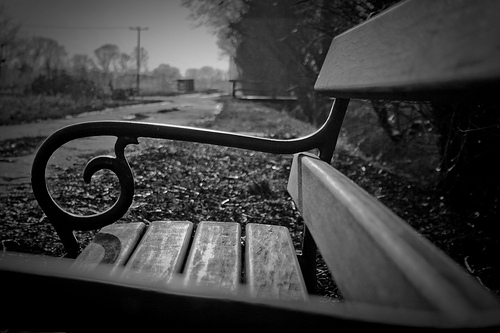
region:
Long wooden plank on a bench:
[305, 20, 468, 117]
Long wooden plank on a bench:
[271, 157, 428, 328]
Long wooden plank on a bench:
[240, 214, 307, 320]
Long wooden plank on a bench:
[189, 205, 240, 305]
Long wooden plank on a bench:
[140, 206, 185, 305]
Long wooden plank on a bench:
[67, 199, 133, 299]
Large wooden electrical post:
[124, 17, 159, 94]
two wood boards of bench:
[285, 0, 497, 307]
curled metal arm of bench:
[28, 99, 343, 232]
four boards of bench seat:
[70, 218, 304, 292]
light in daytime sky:
[3, 2, 234, 82]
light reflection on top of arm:
[58, 100, 337, 142]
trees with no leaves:
[3, 35, 175, 91]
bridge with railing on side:
[230, 76, 299, 101]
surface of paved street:
[2, 91, 228, 192]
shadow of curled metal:
[90, 230, 124, 267]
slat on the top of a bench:
[313, 0, 498, 97]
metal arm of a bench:
[31, 82, 354, 224]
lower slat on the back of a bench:
[282, 148, 491, 328]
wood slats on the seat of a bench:
[56, 205, 309, 316]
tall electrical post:
[126, 18, 152, 99]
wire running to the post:
[11, 20, 135, 35]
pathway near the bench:
[3, 79, 228, 166]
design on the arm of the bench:
[33, 118, 140, 231]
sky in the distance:
[0, 0, 230, 80]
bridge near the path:
[227, 75, 302, 106]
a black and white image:
[1, 1, 473, 331]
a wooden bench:
[14, 10, 494, 331]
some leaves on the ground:
[53, 125, 451, 230]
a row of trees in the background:
[2, 20, 247, 110]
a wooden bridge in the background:
[212, 56, 324, 127]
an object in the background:
[170, 71, 204, 98]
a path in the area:
[0, 83, 231, 200]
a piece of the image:
[278, 169, 294, 185]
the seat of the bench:
[131, 221, 245, 282]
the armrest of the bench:
[162, 122, 257, 145]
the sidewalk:
[183, 95, 203, 114]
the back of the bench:
[373, 39, 453, 89]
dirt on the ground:
[198, 167, 274, 218]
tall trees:
[34, 38, 71, 77]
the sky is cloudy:
[160, 35, 207, 62]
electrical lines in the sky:
[71, 18, 138, 36]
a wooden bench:
[177, 226, 249, 274]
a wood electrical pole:
[126, 17, 149, 98]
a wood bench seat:
[77, 202, 297, 329]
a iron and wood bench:
[40, 0, 462, 327]